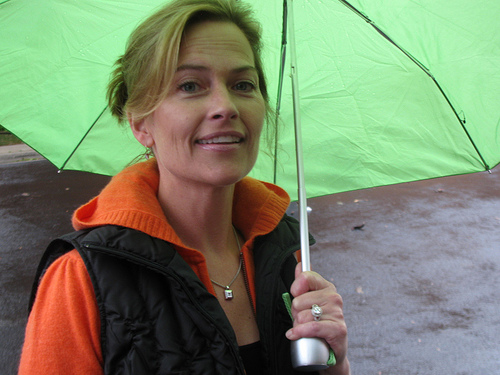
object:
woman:
[18, 0, 347, 375]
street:
[0, 147, 498, 374]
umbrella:
[0, 0, 497, 200]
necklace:
[211, 229, 243, 299]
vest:
[28, 216, 313, 374]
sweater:
[23, 158, 289, 373]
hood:
[75, 163, 288, 244]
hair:
[110, 0, 265, 115]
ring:
[311, 304, 323, 321]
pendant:
[224, 290, 233, 299]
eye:
[177, 81, 207, 93]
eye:
[231, 81, 255, 92]